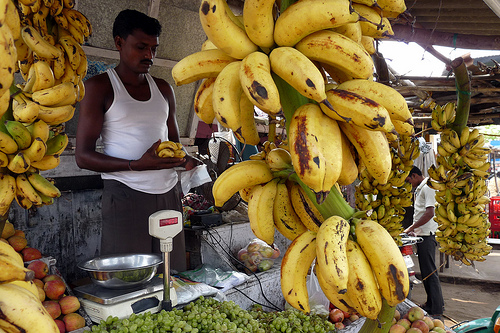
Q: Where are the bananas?
A: Market.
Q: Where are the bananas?
A: Market.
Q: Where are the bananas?
A: Market.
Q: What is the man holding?
A: Bananas.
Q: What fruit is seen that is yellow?
A: Bananas.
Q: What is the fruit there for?
A: Selling.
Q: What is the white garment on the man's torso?
A: Shirt.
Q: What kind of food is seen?
A: Fruit.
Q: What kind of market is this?
A: Open air.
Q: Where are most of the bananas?
A: Hanging.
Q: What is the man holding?
A: Bananas.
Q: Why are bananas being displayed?
A: To be sold.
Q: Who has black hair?
A: The man.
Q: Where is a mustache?
A: On man's face.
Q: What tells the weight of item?
A: Silver scale.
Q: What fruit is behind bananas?
A: Peaches.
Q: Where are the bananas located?
A: Street vendor.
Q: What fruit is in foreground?
A: Green grapes.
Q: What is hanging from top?
A: Bananas.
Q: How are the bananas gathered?
A: In bunches.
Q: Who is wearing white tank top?
A: Man selling bananas.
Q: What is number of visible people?
A: Two.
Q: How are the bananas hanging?
A: Upside down.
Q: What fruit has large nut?
A: Peach.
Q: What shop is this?
A: Fruit shop.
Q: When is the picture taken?
A: Daytime.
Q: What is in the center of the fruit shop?
A: Weight machine.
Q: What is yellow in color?
A: Banana.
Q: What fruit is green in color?
A: Grapes.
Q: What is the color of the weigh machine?
A: White.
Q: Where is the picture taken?
A: In Nepal.